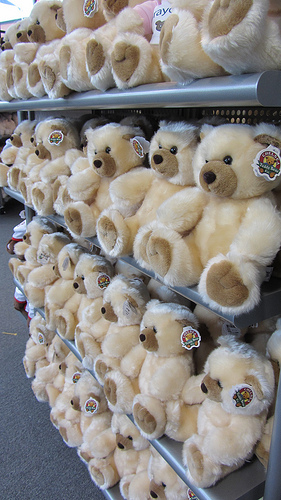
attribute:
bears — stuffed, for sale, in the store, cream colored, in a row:
[2, 0, 279, 499]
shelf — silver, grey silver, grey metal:
[1, 74, 275, 114]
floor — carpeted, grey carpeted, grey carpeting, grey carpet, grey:
[1, 203, 120, 499]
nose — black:
[203, 172, 219, 184]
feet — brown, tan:
[143, 237, 249, 305]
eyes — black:
[153, 142, 233, 167]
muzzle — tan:
[200, 161, 238, 200]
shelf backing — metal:
[145, 105, 281, 125]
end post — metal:
[261, 361, 280, 500]